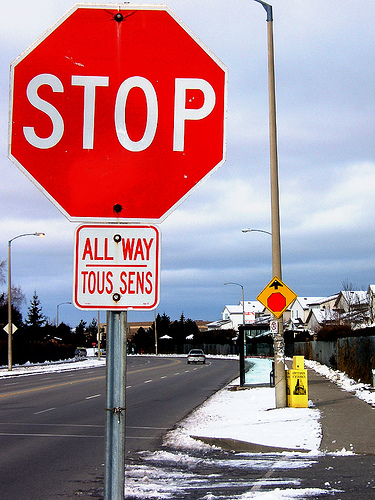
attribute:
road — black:
[4, 281, 360, 496]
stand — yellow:
[283, 351, 313, 411]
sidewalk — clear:
[248, 333, 374, 448]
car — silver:
[188, 348, 207, 365]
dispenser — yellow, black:
[286, 354, 309, 407]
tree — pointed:
[25, 288, 48, 328]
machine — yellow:
[283, 353, 309, 409]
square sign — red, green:
[72, 221, 161, 312]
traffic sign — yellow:
[254, 272, 301, 321]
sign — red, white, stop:
[8, 2, 225, 221]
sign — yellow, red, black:
[252, 274, 299, 317]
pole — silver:
[104, 311, 126, 496]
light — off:
[216, 208, 269, 253]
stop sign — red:
[10, 3, 233, 222]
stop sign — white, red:
[3, 7, 233, 238]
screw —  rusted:
[110, 195, 128, 220]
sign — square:
[40, 215, 231, 355]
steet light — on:
[32, 229, 47, 239]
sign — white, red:
[74, 227, 159, 312]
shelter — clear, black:
[215, 257, 370, 375]